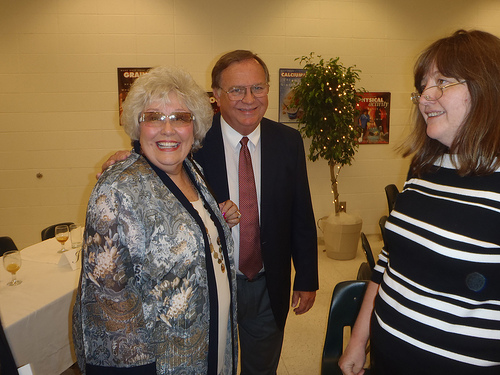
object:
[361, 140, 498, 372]
shirt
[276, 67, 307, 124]
picture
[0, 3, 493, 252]
wall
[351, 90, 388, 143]
picture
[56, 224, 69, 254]
wine glass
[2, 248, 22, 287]
wine glass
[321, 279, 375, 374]
chair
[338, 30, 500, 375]
lady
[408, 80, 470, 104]
glasses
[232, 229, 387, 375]
ground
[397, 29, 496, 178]
brown hair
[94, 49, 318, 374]
man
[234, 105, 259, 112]
smile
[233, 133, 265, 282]
tie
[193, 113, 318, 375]
suit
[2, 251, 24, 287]
glasses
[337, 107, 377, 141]
ground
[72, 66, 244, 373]
lady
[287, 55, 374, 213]
tree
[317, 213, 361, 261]
planter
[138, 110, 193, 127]
glasses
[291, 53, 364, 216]
plant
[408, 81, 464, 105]
glasses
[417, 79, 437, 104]
nose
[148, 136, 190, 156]
lips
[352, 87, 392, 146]
poster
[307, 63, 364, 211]
lights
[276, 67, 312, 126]
poster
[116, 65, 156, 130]
poster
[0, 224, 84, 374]
table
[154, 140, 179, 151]
lipstick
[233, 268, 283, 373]
pants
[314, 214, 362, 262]
pot